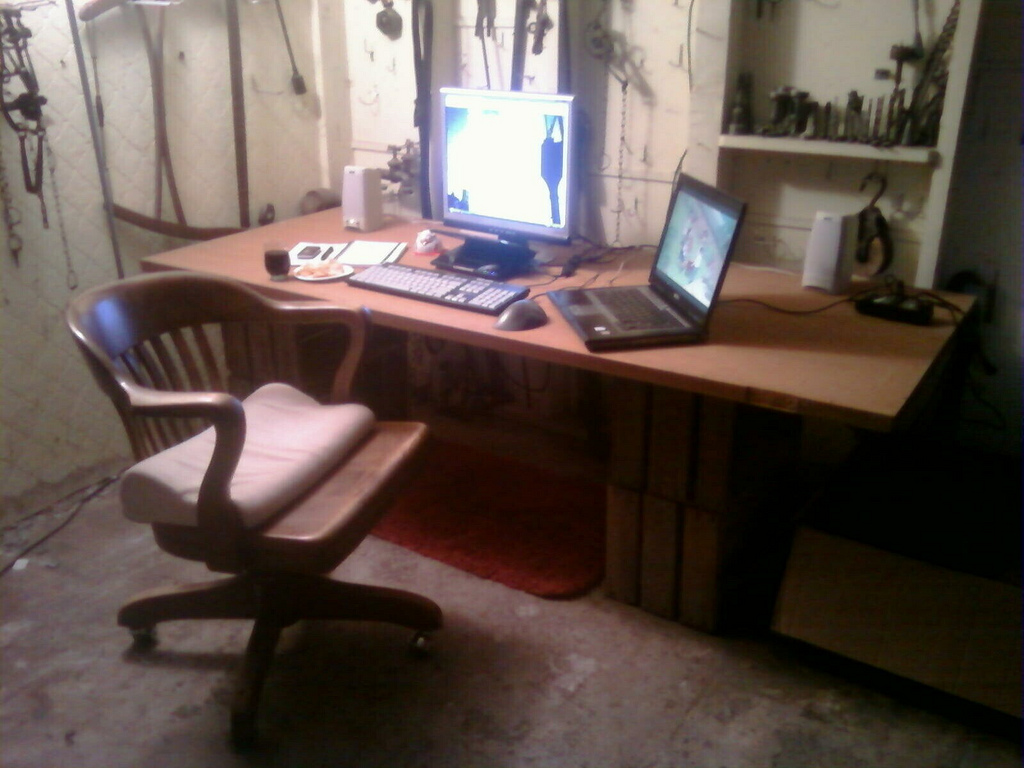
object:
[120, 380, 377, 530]
seat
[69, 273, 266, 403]
back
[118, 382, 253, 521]
right arm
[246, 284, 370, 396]
left arm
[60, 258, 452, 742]
chair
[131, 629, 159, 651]
wheel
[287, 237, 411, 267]
paper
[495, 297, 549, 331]
mouse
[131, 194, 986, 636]
desk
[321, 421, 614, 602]
rug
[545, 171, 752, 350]
laptop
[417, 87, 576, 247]
monitor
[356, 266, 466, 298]
keys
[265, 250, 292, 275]
drink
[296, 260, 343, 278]
food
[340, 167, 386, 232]
speaker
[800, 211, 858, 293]
speaker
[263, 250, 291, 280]
glass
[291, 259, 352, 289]
plate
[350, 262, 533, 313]
keyboard